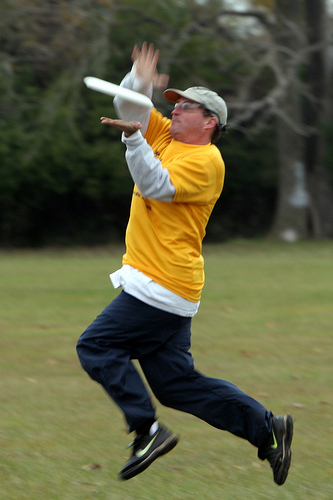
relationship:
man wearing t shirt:
[73, 39, 303, 496] [109, 105, 224, 311]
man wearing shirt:
[73, 39, 303, 496] [122, 108, 224, 306]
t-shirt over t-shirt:
[137, 117, 221, 307] [122, 117, 223, 304]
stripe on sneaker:
[270, 430, 278, 449] [265, 415, 292, 485]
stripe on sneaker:
[136, 430, 157, 457] [117, 423, 178, 481]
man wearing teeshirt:
[73, 39, 303, 496] [105, 266, 200, 321]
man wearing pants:
[73, 39, 303, 496] [67, 285, 268, 452]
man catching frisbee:
[73, 39, 303, 496] [82, 71, 157, 118]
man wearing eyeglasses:
[73, 39, 303, 496] [170, 100, 206, 113]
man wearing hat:
[73, 39, 303, 496] [163, 85, 227, 125]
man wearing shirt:
[73, 39, 303, 496] [131, 96, 219, 301]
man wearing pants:
[73, 39, 303, 496] [77, 293, 236, 411]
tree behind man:
[213, 0, 332, 241] [73, 39, 303, 496]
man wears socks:
[73, 39, 303, 496] [150, 420, 159, 435]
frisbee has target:
[73, 70, 193, 123] [284, 153, 312, 212]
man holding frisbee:
[73, 39, 303, 496] [62, 57, 146, 115]